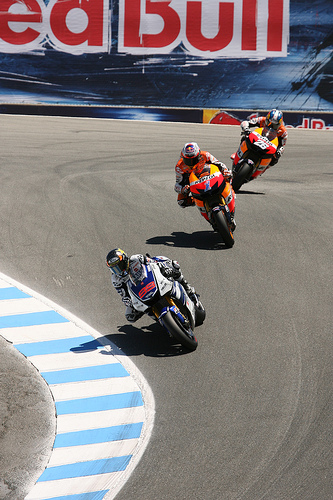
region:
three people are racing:
[84, 62, 331, 371]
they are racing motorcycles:
[48, 66, 328, 392]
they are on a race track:
[76, 62, 319, 393]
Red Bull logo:
[2, 1, 309, 86]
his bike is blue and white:
[78, 220, 252, 379]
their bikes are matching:
[158, 72, 325, 260]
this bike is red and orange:
[160, 128, 257, 251]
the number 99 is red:
[124, 277, 165, 303]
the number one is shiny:
[202, 172, 216, 197]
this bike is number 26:
[237, 81, 310, 196]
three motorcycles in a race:
[98, 67, 302, 359]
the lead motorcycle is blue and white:
[73, 215, 257, 380]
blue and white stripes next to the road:
[63, 279, 92, 489]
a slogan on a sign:
[10, 0, 293, 59]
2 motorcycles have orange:
[179, 91, 290, 249]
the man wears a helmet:
[92, 234, 137, 275]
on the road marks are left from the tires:
[67, 144, 199, 268]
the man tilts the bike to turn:
[158, 135, 277, 253]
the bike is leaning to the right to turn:
[101, 245, 236, 360]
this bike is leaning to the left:
[234, 95, 291, 190]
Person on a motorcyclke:
[80, 229, 213, 368]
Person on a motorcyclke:
[150, 120, 244, 280]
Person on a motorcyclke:
[223, 102, 299, 203]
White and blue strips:
[25, 464, 82, 498]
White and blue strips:
[46, 426, 118, 454]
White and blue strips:
[54, 388, 118, 432]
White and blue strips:
[33, 344, 92, 391]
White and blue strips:
[15, 317, 103, 371]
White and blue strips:
[4, 293, 64, 334]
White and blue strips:
[0, 258, 162, 499]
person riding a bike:
[96, 236, 218, 354]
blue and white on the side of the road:
[58, 366, 120, 407]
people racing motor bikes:
[156, 108, 301, 253]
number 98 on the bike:
[135, 278, 159, 298]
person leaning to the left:
[167, 136, 243, 247]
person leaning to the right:
[221, 107, 292, 190]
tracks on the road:
[264, 347, 322, 438]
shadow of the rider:
[63, 318, 136, 364]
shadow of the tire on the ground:
[245, 189, 271, 199]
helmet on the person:
[102, 247, 131, 276]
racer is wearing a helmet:
[91, 236, 136, 283]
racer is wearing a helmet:
[175, 135, 217, 166]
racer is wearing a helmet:
[257, 104, 292, 138]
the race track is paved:
[157, 304, 314, 413]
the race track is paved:
[179, 333, 287, 442]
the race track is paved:
[36, 202, 162, 247]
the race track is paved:
[210, 357, 289, 413]